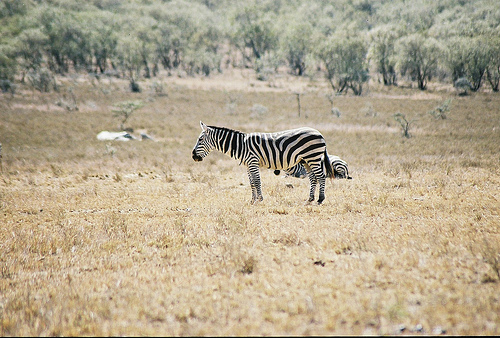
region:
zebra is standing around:
[192, 122, 330, 203]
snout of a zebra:
[192, 150, 202, 161]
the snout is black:
[191, 148, 201, 161]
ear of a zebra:
[200, 120, 205, 131]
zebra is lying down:
[273, 156, 351, 178]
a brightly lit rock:
[98, 130, 133, 140]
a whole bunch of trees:
[1, 0, 498, 94]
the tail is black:
[323, 150, 333, 177]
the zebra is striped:
[193, 122, 333, 204]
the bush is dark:
[130, 80, 139, 92]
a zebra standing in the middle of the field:
[186, 120, 333, 208]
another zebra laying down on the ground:
[271, 155, 350, 178]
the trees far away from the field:
[2, 2, 497, 87]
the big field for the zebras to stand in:
[15, 90, 497, 335]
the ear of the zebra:
[197, 118, 205, 133]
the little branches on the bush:
[466, 233, 497, 279]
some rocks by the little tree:
[95, 128, 151, 141]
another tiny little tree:
[391, 107, 411, 133]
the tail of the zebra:
[320, 155, 331, 175]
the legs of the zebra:
[240, 163, 327, 208]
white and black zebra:
[182, 131, 328, 190]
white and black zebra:
[332, 148, 357, 173]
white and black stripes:
[244, 138, 300, 157]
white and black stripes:
[329, 160, 352, 180]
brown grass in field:
[117, 216, 309, 293]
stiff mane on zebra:
[209, 112, 246, 132]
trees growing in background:
[19, 12, 468, 76]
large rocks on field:
[90, 119, 135, 141]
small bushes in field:
[379, 108, 431, 150]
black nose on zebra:
[189, 149, 208, 168]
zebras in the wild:
[167, 110, 367, 222]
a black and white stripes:
[179, 108, 341, 225]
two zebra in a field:
[148, 64, 450, 265]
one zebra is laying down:
[278, 131, 368, 208]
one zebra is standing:
[181, 106, 390, 218]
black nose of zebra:
[189, 147, 207, 164]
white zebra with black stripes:
[177, 107, 338, 231]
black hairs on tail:
[322, 148, 340, 187]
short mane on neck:
[206, 121, 246, 141]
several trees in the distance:
[21, 7, 498, 120]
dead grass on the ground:
[26, 72, 498, 337]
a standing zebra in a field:
[168, 102, 370, 238]